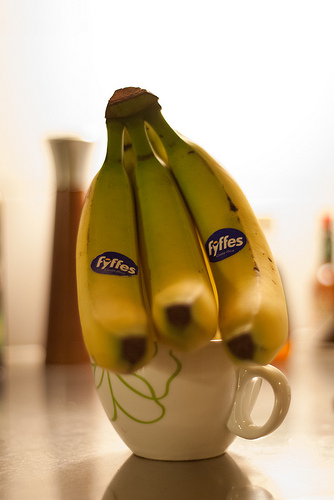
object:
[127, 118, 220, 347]
banana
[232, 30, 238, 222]
donuts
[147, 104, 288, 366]
banana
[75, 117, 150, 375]
banana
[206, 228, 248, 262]
label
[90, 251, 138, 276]
label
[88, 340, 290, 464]
cup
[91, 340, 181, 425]
flower design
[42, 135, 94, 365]
ketchup bottle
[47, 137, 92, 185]
lid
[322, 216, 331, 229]
lid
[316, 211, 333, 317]
sauce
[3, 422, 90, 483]
table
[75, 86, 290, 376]
three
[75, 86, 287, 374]
bunch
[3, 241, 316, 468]
front view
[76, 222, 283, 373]
them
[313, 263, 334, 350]
bottle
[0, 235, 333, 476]
background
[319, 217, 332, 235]
red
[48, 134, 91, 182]
white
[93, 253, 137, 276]
"fyffes"